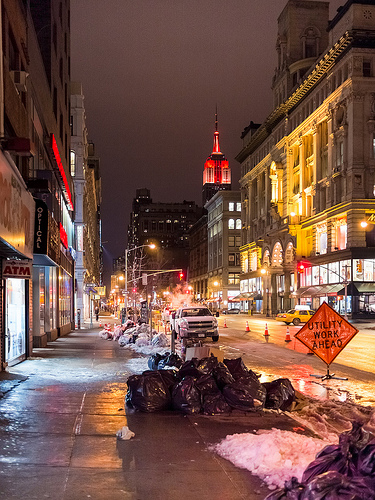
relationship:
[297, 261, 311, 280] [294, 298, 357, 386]
red light in sign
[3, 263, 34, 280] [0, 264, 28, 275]
sign in letters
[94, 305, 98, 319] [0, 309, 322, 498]
man down sidewalk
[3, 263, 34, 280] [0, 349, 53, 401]
sign for atm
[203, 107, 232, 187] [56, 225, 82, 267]
top of a building lit up red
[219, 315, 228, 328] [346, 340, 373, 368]
cone on road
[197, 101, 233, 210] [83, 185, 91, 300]
building lit up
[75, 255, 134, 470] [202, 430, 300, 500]
city street at night during winter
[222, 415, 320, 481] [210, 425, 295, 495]
snow that has not yet melted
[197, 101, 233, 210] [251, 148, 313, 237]
building in distance with lighting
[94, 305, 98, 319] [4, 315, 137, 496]
man walking down sidewalk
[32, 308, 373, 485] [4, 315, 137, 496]
snow/ice on sidewalk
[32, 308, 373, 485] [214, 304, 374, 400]
snow/ice on street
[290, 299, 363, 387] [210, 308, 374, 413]
sign on road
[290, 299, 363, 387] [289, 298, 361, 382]
sign warns of utility work